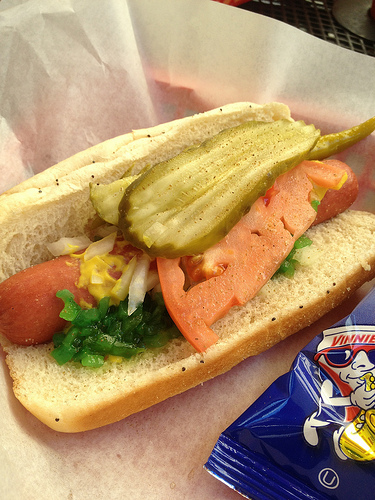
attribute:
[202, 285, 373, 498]
bag —   blue,  of snacks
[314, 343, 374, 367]
sunglasses — red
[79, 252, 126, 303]
mustard — yellow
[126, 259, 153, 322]
onion — chopped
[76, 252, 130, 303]
dog — hot